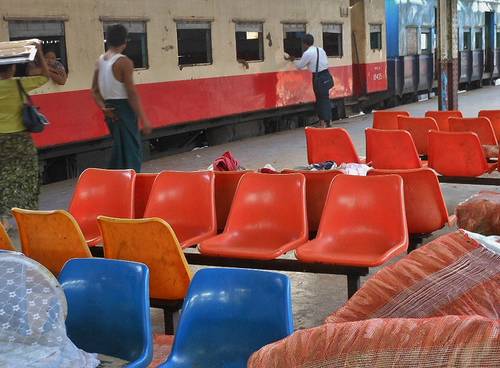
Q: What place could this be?
A: It is a train station.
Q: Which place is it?
A: It is a train station.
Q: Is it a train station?
A: Yes, it is a train station.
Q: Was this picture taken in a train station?
A: Yes, it was taken in a train station.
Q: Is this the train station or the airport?
A: It is the train station.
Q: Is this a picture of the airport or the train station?
A: It is showing the train station.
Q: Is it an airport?
A: No, it is a train station.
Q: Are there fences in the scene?
A: No, there are no fences.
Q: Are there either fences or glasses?
A: No, there are no fences or glasses.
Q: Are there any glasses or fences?
A: No, there are no fences or glasses.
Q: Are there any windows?
A: Yes, there is a window.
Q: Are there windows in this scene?
A: Yes, there is a window.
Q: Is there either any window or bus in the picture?
A: Yes, there is a window.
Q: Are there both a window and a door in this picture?
A: No, there is a window but no doors.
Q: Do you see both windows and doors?
A: No, there is a window but no doors.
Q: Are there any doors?
A: No, there are no doors.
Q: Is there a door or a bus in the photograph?
A: No, there are no doors or buses.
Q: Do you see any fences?
A: No, there are no fences.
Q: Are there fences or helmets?
A: No, there are no fences or helmets.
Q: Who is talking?
A: The man is talking.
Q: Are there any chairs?
A: Yes, there is a chair.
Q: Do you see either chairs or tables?
A: Yes, there is a chair.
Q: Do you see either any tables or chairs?
A: Yes, there is a chair.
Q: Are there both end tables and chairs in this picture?
A: No, there is a chair but no end tables.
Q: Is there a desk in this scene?
A: No, there are no desks.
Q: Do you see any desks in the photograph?
A: No, there are no desks.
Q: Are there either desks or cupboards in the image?
A: No, there are no desks or cupboards.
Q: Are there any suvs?
A: No, there are no suvs.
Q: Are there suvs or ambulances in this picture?
A: No, there are no suvs or ambulances.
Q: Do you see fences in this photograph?
A: No, there are no fences.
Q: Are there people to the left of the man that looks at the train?
A: Yes, there is a person to the left of the man.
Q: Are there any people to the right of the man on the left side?
A: No, the person is to the left of the man.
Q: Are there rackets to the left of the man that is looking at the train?
A: No, there is a person to the left of the man.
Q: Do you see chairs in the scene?
A: Yes, there is a chair.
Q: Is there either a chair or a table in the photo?
A: Yes, there is a chair.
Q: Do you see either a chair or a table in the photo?
A: Yes, there is a chair.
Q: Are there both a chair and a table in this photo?
A: No, there is a chair but no tables.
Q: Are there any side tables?
A: No, there are no side tables.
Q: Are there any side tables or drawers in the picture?
A: No, there are no side tables or drawers.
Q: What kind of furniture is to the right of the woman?
A: The piece of furniture is a chair.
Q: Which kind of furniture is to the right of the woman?
A: The piece of furniture is a chair.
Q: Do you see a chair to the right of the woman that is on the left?
A: Yes, there is a chair to the right of the woman.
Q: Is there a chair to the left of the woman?
A: No, the chair is to the right of the woman.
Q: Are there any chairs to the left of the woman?
A: No, the chair is to the right of the woman.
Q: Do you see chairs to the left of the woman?
A: No, the chair is to the right of the woman.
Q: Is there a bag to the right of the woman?
A: No, there is a chair to the right of the woman.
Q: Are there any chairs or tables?
A: Yes, there is a chair.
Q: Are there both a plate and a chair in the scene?
A: No, there is a chair but no plates.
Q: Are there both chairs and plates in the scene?
A: No, there is a chair but no plates.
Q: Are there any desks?
A: No, there are no desks.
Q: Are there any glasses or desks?
A: No, there are no desks or glasses.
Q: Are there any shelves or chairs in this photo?
A: Yes, there is a chair.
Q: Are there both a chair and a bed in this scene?
A: No, there is a chair but no beds.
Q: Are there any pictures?
A: No, there are no pictures.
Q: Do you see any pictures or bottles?
A: No, there are no pictures or bottles.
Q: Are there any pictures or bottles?
A: No, there are no pictures or bottles.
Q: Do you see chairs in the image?
A: Yes, there is a chair.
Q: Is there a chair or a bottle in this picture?
A: Yes, there is a chair.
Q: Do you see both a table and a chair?
A: No, there is a chair but no tables.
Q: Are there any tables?
A: No, there are no tables.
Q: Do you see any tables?
A: No, there are no tables.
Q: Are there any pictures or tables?
A: No, there are no tables or pictures.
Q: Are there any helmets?
A: No, there are no helmets.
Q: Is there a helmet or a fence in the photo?
A: No, there are no helmets or fences.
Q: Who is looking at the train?
A: The man is looking at the train.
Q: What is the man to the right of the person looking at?
A: The man is looking at the train.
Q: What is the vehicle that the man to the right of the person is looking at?
A: The vehicle is a train.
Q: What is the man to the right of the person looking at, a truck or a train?
A: The man is looking at a train.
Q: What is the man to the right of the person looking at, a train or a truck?
A: The man is looking at a train.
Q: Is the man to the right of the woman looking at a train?
A: Yes, the man is looking at a train.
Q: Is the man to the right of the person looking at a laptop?
A: No, the man is looking at a train.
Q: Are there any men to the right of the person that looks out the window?
A: Yes, there is a man to the right of the person.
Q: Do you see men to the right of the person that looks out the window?
A: Yes, there is a man to the right of the person.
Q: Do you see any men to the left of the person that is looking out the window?
A: No, the man is to the right of the person.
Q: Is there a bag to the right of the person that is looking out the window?
A: No, there is a man to the right of the person.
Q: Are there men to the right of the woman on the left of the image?
A: Yes, there is a man to the right of the woman.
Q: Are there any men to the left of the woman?
A: No, the man is to the right of the woman.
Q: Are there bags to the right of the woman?
A: No, there is a man to the right of the woman.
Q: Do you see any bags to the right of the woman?
A: No, there is a man to the right of the woman.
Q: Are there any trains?
A: Yes, there is a train.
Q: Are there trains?
A: Yes, there is a train.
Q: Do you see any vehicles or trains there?
A: Yes, there is a train.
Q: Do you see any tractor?
A: No, there are no tractors.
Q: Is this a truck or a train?
A: This is a train.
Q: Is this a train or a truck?
A: This is a train.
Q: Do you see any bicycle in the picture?
A: No, there are no bicycles.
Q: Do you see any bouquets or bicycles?
A: No, there are no bicycles or bouquets.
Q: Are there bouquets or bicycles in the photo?
A: No, there are no bicycles or bouquets.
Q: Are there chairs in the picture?
A: Yes, there is a chair.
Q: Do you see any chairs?
A: Yes, there is a chair.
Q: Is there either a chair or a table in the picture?
A: Yes, there is a chair.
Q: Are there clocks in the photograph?
A: No, there are no clocks.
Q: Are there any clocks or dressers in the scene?
A: No, there are no clocks or dressers.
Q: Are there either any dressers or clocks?
A: No, there are no clocks or dressers.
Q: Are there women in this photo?
A: Yes, there is a woman.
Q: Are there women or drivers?
A: Yes, there is a woman.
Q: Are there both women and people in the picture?
A: Yes, there are both a woman and people.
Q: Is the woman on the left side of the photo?
A: Yes, the woman is on the left of the image.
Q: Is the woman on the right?
A: No, the woman is on the left of the image.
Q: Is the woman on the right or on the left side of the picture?
A: The woman is on the left of the image.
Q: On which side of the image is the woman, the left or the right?
A: The woman is on the left of the image.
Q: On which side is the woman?
A: The woman is on the left of the image.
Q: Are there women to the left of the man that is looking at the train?
A: Yes, there is a woman to the left of the man.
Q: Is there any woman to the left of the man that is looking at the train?
A: Yes, there is a woman to the left of the man.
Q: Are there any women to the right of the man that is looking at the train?
A: No, the woman is to the left of the man.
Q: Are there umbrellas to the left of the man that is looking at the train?
A: No, there is a woman to the left of the man.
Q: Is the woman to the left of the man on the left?
A: Yes, the woman is to the left of the man.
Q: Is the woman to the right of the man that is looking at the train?
A: No, the woman is to the left of the man.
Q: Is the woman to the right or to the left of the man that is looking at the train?
A: The woman is to the left of the man.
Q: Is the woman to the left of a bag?
A: No, the woman is to the left of the chair.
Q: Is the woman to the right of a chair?
A: No, the woman is to the left of a chair.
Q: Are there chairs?
A: Yes, there is a chair.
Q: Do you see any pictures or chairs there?
A: Yes, there is a chair.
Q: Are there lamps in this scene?
A: No, there are no lamps.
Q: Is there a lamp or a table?
A: No, there are no lamps or tables.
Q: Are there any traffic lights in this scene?
A: No, there are no traffic lights.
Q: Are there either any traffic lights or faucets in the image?
A: No, there are no traffic lights or faucets.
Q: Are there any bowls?
A: No, there are no bowls.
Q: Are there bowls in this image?
A: No, there are no bowls.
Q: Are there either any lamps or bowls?
A: No, there are no bowls or lamps.